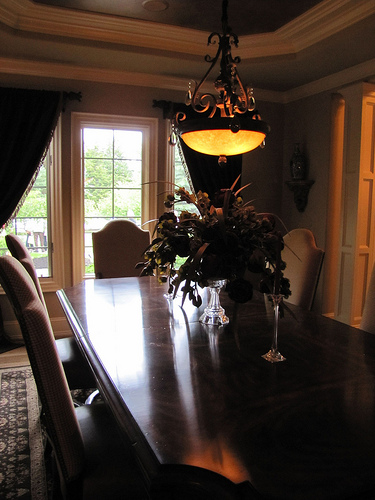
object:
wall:
[282, 14, 374, 313]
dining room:
[2, 1, 375, 500]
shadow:
[137, 301, 190, 437]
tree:
[140, 174, 287, 323]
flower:
[137, 178, 296, 360]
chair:
[92, 220, 151, 278]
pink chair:
[62, 119, 179, 283]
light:
[169, 114, 272, 163]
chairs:
[3, 233, 102, 454]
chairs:
[263, 225, 325, 310]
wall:
[279, 94, 331, 230]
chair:
[0, 245, 133, 480]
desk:
[61, 270, 374, 499]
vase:
[199, 273, 232, 326]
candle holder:
[261, 293, 287, 363]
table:
[49, 257, 374, 374]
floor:
[2, 342, 106, 498]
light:
[173, 436, 251, 486]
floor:
[1, 339, 43, 497]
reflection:
[83, 270, 219, 443]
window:
[70, 113, 157, 281]